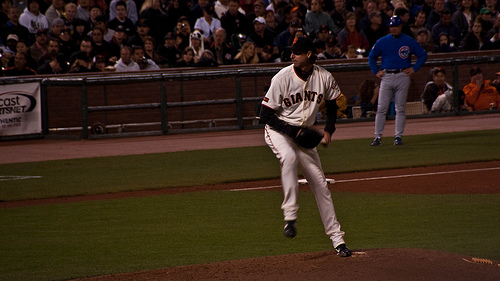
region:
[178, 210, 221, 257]
part of a green ground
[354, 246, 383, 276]
part of a ground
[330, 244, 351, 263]
edge of a shoe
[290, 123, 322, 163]
part of a glove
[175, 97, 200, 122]
part of a fence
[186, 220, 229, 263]
part of a field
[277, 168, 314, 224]
part of a trouser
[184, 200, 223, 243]
part of a field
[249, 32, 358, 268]
this is a baseball player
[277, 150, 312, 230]
the leg is up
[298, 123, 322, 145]
he is wearing a glove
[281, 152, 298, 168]
the knee is bent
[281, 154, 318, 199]
the trousers are white in color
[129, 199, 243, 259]
the grass is treamed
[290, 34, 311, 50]
he is wearing a cap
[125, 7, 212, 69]
the spectators are watching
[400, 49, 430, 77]
the hand is in the pocket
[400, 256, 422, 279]
the pitch is brown in color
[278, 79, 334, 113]
Giants on the jersey.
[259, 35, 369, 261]
Pitcher on the mound.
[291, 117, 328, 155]
Pitcher holding a mitt.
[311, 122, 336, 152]
Pitcher has a ball.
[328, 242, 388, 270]
Base on the mound.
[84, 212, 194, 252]
The grass is green.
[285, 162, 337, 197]
Base behind the pitcher.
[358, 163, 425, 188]
White line on the ground.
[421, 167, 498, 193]
The path is dirt covered.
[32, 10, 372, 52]
People in the stand.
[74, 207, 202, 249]
The grass is green.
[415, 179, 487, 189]
The dirt is brown.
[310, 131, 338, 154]
The person is holding a baseball.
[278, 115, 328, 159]
The person is wearing a mitt.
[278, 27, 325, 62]
The person is wearing a hat.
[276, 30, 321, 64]
The hat is black.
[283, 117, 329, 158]
The mitt is black.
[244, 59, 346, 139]
The person is wearing a white shirt.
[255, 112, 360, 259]
The pants are white.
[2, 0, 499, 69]
The stands are full.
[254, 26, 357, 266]
baseball pitcher on mound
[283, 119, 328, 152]
baseball glove on hand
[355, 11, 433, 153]
man in uniform standing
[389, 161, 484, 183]
white line in dirt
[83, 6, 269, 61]
people sitting in stands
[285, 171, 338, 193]
white base in dirt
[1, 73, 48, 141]
white banner with logo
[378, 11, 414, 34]
shine on batter's helmet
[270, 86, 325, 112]
name of team on shirt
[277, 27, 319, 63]
baseball cap on head